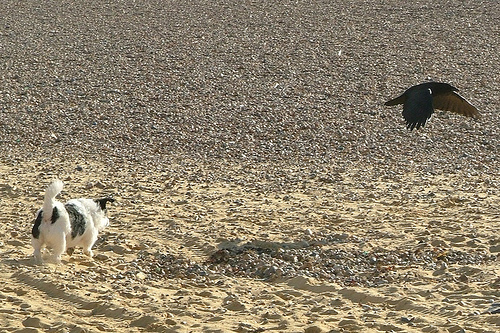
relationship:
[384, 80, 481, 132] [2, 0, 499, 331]
bird flying on sand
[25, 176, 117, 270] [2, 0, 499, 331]
dog on sand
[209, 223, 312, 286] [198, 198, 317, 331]
rocks on ground